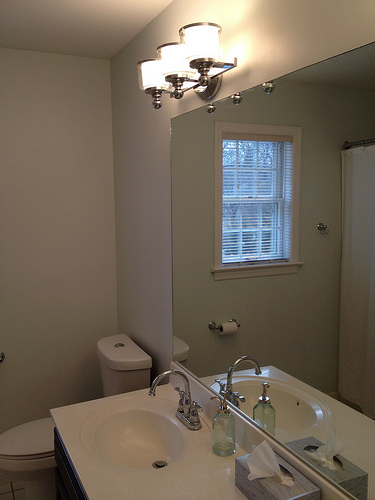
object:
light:
[178, 19, 222, 62]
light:
[156, 40, 187, 80]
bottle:
[209, 388, 237, 459]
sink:
[90, 408, 190, 480]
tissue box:
[231, 440, 321, 500]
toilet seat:
[1, 450, 58, 461]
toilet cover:
[1, 415, 57, 455]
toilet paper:
[207, 318, 241, 338]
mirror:
[169, 42, 375, 499]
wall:
[1, 44, 121, 431]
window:
[221, 138, 239, 170]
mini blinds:
[221, 136, 286, 266]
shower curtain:
[338, 145, 375, 414]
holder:
[208, 318, 242, 331]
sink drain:
[151, 460, 169, 471]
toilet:
[0, 333, 153, 499]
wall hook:
[316, 221, 332, 237]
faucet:
[149, 368, 204, 433]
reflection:
[208, 114, 375, 499]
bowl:
[0, 454, 58, 476]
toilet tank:
[96, 333, 153, 397]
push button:
[114, 342, 126, 349]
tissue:
[246, 439, 283, 482]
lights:
[136, 57, 166, 92]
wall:
[109, 0, 375, 393]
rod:
[342, 134, 375, 150]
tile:
[2, 479, 13, 491]